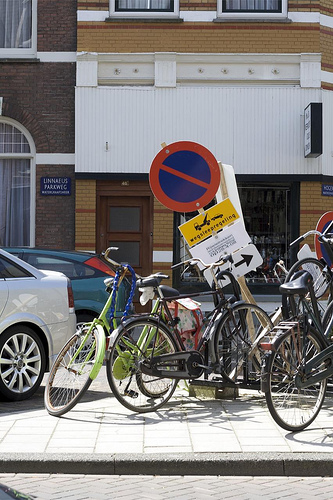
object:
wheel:
[0, 326, 46, 401]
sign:
[320, 183, 333, 197]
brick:
[301, 179, 323, 225]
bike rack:
[203, 310, 331, 396]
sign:
[148, 140, 220, 213]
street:
[0, 290, 332, 497]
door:
[96, 173, 152, 312]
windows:
[105, 200, 142, 270]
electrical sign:
[303, 101, 324, 159]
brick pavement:
[0, 470, 331, 499]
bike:
[105, 252, 280, 415]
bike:
[255, 220, 333, 433]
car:
[0, 245, 77, 401]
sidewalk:
[0, 361, 333, 472]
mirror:
[237, 181, 291, 291]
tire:
[106, 312, 182, 413]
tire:
[263, 324, 328, 432]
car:
[1, 244, 137, 363]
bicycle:
[43, 246, 179, 417]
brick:
[223, 36, 238, 44]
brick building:
[0, 0, 76, 249]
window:
[0, 114, 35, 248]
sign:
[178, 196, 241, 249]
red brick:
[0, 471, 333, 500]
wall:
[25, 53, 99, 213]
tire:
[211, 300, 280, 388]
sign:
[39, 175, 71, 196]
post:
[215, 159, 262, 366]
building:
[74, 164, 333, 311]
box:
[159, 297, 206, 353]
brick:
[0, 0, 76, 256]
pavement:
[0, 356, 333, 466]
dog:
[278, 268, 282, 278]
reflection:
[182, 175, 298, 280]